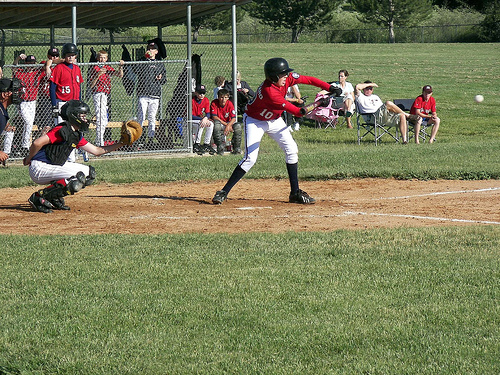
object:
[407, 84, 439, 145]
people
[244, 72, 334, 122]
jersey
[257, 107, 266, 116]
number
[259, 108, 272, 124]
10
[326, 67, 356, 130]
people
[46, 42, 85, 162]
players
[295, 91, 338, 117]
baseball bat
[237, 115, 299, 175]
pant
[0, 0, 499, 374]
background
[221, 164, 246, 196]
socks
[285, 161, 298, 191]
socks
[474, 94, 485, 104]
ball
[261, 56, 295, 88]
batting helmet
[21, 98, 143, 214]
catcher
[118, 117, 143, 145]
glove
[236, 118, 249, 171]
stripe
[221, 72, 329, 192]
uniform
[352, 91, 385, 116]
shirt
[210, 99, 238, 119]
shirt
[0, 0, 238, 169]
dugout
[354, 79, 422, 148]
man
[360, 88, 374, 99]
covering face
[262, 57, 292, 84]
hat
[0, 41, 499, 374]
game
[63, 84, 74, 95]
numbers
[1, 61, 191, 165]
fence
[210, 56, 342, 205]
he